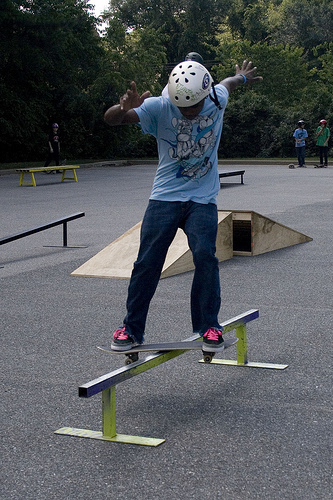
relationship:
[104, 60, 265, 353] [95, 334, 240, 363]
boy on skateboard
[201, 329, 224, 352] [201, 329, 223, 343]
tennis shoe with strings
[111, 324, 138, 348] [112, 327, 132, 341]
tennis shoe with strings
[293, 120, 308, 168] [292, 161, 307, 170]
boy on skateboard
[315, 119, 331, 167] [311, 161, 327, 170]
boy on skateboard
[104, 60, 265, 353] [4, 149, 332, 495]
boy in skateboard park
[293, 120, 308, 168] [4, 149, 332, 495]
boy in skateboard park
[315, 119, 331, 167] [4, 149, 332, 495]
boy in skateboard park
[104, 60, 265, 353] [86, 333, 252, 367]
boy performing trick on skateboard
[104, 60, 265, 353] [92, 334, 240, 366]
boy with skateboard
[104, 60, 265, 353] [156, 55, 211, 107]
boy wearing helmet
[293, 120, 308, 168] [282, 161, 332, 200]
boy standing on floor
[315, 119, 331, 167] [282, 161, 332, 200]
boy standing on floor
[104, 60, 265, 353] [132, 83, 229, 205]
boy wearing shirt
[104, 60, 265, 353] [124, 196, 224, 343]
boy wearing blue jeans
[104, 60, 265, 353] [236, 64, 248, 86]
boy wearing wrist band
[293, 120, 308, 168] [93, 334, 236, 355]
boy doing stunt on skateboard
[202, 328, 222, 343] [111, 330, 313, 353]
shoelaces on tennis shoes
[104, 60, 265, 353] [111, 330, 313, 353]
boy wearing tennis shoes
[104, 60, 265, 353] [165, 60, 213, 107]
boy wearing helmet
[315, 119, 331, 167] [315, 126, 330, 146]
boy wearing shirt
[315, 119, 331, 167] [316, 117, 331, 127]
boy wearing helmet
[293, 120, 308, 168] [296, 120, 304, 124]
boy wearing safety helmet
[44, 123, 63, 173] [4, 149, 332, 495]
boy walking across skateboard park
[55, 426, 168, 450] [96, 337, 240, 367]
part of skateboard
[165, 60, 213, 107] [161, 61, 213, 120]
helmet on head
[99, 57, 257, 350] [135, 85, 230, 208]
boy wearing shirt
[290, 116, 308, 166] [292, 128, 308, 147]
boy wearing shirt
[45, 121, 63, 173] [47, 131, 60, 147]
boy wearing shirt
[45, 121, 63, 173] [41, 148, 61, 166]
boy wearing pants